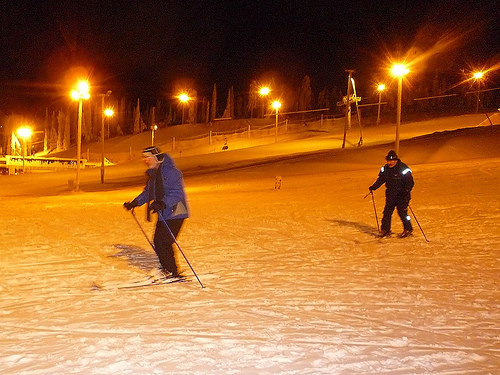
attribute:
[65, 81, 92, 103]
light — outdoors, yellow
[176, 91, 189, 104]
light — outdoors, yellow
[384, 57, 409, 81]
light — outdoors, yellow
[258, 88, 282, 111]
light — outdoors, yellow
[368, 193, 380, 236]
ski pole — black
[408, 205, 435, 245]
ski pole — black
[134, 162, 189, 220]
coat — blue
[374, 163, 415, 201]
coat — black, white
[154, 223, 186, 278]
snow pants — black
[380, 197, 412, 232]
snow pants — black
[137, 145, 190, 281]
person — skiing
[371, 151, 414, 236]
person — skiing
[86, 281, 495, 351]
snow — white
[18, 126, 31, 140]
light — outdoors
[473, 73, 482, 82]
light — outdoors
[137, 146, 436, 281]
people — snowboarding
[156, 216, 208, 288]
ski pole — blue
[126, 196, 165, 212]
gloves — black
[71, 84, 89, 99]
lamp — orange